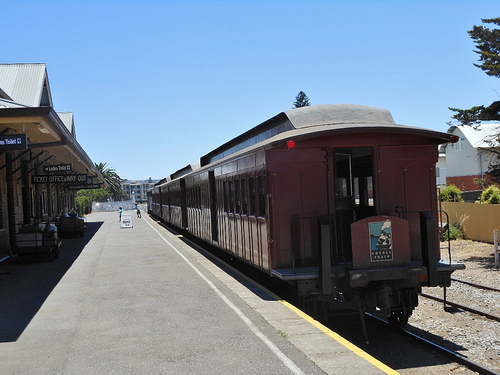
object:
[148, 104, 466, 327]
train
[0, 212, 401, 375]
sidewalk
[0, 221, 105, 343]
shadow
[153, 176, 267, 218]
windows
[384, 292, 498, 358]
tracks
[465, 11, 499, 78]
tree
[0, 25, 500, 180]
sky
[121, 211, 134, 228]
sign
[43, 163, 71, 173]
sign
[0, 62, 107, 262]
building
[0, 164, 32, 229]
wall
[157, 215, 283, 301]
shadow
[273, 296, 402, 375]
line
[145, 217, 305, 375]
line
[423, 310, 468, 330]
gravel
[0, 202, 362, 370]
platform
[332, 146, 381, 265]
door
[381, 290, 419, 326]
wheel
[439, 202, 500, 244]
fence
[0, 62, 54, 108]
roofs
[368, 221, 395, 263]
logo